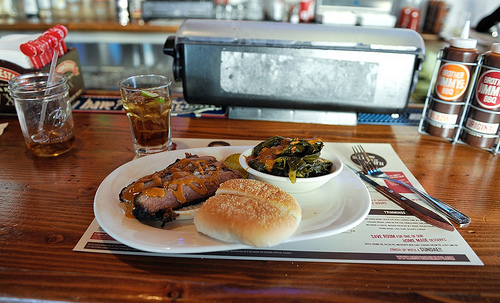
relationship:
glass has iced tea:
[120, 72, 172, 153] [125, 93, 174, 149]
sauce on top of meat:
[118, 156, 224, 210] [118, 153, 234, 223]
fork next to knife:
[353, 142, 467, 228] [342, 159, 452, 231]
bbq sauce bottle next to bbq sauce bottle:
[414, 20, 482, 142] [459, 39, 500, 151]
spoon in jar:
[33, 48, 64, 138] [9, 72, 77, 157]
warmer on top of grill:
[163, 18, 422, 112] [224, 104, 360, 128]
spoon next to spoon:
[22, 41, 40, 70] [31, 39, 46, 70]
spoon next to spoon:
[35, 39, 52, 66] [40, 35, 54, 66]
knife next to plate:
[342, 159, 452, 231] [93, 145, 373, 252]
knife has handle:
[342, 159, 452, 231] [378, 183, 451, 233]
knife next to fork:
[342, 159, 452, 231] [353, 142, 467, 228]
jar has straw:
[9, 72, 77, 157] [36, 46, 67, 139]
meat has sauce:
[118, 153, 234, 223] [118, 156, 224, 210]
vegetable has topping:
[248, 132, 330, 180] [259, 133, 317, 177]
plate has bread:
[93, 145, 373, 252] [197, 175, 296, 242]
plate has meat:
[93, 145, 373, 252] [118, 153, 234, 223]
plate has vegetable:
[93, 145, 373, 252] [248, 132, 330, 180]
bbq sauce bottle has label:
[414, 20, 482, 142] [437, 61, 470, 104]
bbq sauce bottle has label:
[459, 39, 500, 151] [473, 67, 499, 112]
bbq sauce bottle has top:
[414, 20, 482, 142] [448, 19, 475, 48]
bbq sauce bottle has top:
[459, 39, 500, 151] [490, 32, 498, 48]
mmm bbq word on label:
[435, 74, 470, 99] [437, 61, 470, 104]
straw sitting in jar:
[36, 46, 67, 139] [9, 72, 77, 157]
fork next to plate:
[353, 142, 467, 228] [93, 145, 373, 252]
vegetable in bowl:
[248, 132, 330, 180] [236, 145, 348, 193]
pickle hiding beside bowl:
[224, 151, 248, 175] [236, 145, 348, 193]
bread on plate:
[197, 175, 296, 242] [93, 145, 373, 252]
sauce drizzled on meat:
[118, 156, 224, 210] [118, 153, 234, 223]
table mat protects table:
[68, 137, 485, 273] [0, 109, 497, 302]